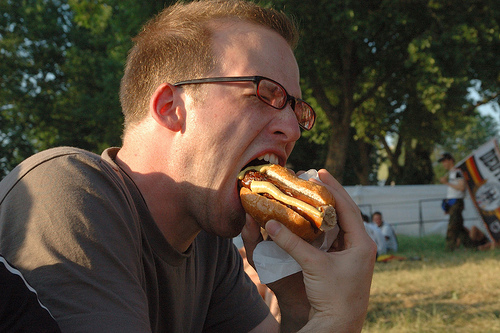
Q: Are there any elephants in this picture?
A: No, there are no elephants.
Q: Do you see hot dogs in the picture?
A: Yes, there is a hot dog.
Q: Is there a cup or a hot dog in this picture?
A: Yes, there is a hot dog.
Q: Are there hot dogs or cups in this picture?
A: Yes, there is a hot dog.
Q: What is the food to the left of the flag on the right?
A: The food is a hot dog.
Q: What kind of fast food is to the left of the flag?
A: The food is a hot dog.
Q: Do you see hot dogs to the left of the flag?
A: Yes, there is a hot dog to the left of the flag.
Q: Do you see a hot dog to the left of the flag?
A: Yes, there is a hot dog to the left of the flag.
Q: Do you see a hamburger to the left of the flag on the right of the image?
A: No, there is a hot dog to the left of the flag.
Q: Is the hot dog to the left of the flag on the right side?
A: Yes, the hot dog is to the left of the flag.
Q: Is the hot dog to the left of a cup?
A: No, the hot dog is to the left of the flag.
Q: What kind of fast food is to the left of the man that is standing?
A: The food is a hot dog.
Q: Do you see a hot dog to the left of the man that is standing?
A: Yes, there is a hot dog to the left of the man.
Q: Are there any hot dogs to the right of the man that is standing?
A: No, the hot dog is to the left of the man.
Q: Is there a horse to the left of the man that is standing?
A: No, there is a hot dog to the left of the man.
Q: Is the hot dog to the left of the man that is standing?
A: Yes, the hot dog is to the left of the man.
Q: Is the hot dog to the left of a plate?
A: No, the hot dog is to the left of the man.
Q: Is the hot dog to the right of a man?
A: No, the hot dog is to the left of a man.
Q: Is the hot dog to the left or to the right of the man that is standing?
A: The hot dog is to the left of the man.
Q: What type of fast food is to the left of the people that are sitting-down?
A: The food is a hot dog.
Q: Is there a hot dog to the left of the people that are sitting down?
A: Yes, there is a hot dog to the left of the people.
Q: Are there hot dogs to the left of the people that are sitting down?
A: Yes, there is a hot dog to the left of the people.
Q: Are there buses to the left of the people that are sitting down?
A: No, there is a hot dog to the left of the people.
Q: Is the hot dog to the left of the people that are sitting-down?
A: Yes, the hot dog is to the left of the people.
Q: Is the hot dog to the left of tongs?
A: No, the hot dog is to the left of the people.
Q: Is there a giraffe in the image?
A: No, there are no giraffes.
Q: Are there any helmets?
A: No, there are no helmets.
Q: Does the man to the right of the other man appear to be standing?
A: Yes, the man is standing.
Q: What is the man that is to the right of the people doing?
A: The man is standing.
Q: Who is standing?
A: The man is standing.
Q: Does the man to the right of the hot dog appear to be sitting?
A: No, the man is standing.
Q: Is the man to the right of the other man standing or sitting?
A: The man is standing.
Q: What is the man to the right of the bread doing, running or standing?
A: The man is standing.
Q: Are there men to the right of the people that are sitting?
A: Yes, there is a man to the right of the people.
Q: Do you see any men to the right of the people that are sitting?
A: Yes, there is a man to the right of the people.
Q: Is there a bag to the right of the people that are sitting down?
A: No, there is a man to the right of the people.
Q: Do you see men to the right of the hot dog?
A: Yes, there is a man to the right of the hot dog.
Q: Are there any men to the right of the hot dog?
A: Yes, there is a man to the right of the hot dog.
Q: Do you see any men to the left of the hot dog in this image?
A: No, the man is to the right of the hot dog.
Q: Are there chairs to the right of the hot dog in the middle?
A: No, there is a man to the right of the hot dog.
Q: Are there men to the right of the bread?
A: Yes, there is a man to the right of the bread.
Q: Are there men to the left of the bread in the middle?
A: No, the man is to the right of the bread.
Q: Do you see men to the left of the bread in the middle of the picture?
A: No, the man is to the right of the bread.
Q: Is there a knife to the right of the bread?
A: No, there is a man to the right of the bread.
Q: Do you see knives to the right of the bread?
A: No, there is a man to the right of the bread.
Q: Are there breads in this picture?
A: Yes, there is a bread.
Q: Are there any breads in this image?
A: Yes, there is a bread.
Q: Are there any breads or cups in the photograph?
A: Yes, there is a bread.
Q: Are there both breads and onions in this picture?
A: No, there is a bread but no onions.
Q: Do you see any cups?
A: No, there are no cups.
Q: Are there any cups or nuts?
A: No, there are no cups or nuts.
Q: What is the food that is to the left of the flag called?
A: The food is a bread.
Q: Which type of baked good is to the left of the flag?
A: The food is a bread.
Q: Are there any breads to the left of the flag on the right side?
A: Yes, there is a bread to the left of the flag.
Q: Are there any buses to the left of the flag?
A: No, there is a bread to the left of the flag.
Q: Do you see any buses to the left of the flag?
A: No, there is a bread to the left of the flag.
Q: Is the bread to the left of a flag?
A: Yes, the bread is to the left of a flag.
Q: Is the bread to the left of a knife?
A: No, the bread is to the left of a flag.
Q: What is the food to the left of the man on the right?
A: The food is a bread.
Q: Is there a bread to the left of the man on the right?
A: Yes, there is a bread to the left of the man.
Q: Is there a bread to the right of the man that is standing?
A: No, the bread is to the left of the man.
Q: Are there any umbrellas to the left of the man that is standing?
A: No, there is a bread to the left of the man.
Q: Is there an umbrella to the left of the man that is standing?
A: No, there is a bread to the left of the man.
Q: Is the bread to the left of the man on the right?
A: Yes, the bread is to the left of the man.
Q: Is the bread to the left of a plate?
A: No, the bread is to the left of the man.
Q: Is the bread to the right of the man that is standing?
A: No, the bread is to the left of the man.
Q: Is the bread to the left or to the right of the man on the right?
A: The bread is to the left of the man.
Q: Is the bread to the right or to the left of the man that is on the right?
A: The bread is to the left of the man.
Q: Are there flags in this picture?
A: Yes, there is a flag.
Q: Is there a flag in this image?
A: Yes, there is a flag.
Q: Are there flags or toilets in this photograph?
A: Yes, there is a flag.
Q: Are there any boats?
A: No, there are no boats.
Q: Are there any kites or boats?
A: No, there are no boats or kites.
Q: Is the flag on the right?
A: Yes, the flag is on the right of the image.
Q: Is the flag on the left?
A: No, the flag is on the right of the image.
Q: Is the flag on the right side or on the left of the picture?
A: The flag is on the right of the image.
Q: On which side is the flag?
A: The flag is on the right of the image.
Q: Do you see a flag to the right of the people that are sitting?
A: Yes, there is a flag to the right of the people.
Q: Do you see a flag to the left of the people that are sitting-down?
A: No, the flag is to the right of the people.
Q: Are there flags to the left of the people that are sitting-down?
A: No, the flag is to the right of the people.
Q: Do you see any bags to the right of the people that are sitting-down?
A: No, there is a flag to the right of the people.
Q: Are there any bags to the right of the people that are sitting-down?
A: No, there is a flag to the right of the people.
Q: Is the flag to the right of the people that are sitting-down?
A: Yes, the flag is to the right of the people.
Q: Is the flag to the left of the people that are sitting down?
A: No, the flag is to the right of the people.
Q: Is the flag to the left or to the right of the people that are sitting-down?
A: The flag is to the right of the people.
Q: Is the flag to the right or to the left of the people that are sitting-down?
A: The flag is to the right of the people.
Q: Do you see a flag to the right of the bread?
A: Yes, there is a flag to the right of the bread.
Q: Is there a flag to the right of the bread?
A: Yes, there is a flag to the right of the bread.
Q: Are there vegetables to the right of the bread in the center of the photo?
A: No, there is a flag to the right of the bread.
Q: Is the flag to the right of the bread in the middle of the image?
A: Yes, the flag is to the right of the bread.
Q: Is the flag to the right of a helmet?
A: No, the flag is to the right of the bread.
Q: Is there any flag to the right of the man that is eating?
A: Yes, there is a flag to the right of the man.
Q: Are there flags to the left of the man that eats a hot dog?
A: No, the flag is to the right of the man.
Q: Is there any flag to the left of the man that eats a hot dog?
A: No, the flag is to the right of the man.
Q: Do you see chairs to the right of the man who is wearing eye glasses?
A: No, there is a flag to the right of the man.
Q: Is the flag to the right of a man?
A: Yes, the flag is to the right of a man.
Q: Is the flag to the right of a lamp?
A: No, the flag is to the right of a man.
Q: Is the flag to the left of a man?
A: No, the flag is to the right of a man.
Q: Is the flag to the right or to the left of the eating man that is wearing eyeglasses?
A: The flag is to the right of the man.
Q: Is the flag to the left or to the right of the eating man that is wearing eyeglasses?
A: The flag is to the right of the man.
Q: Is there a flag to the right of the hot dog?
A: Yes, there is a flag to the right of the hot dog.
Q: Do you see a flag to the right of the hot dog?
A: Yes, there is a flag to the right of the hot dog.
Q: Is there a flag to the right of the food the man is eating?
A: Yes, there is a flag to the right of the hot dog.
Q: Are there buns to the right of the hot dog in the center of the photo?
A: No, there is a flag to the right of the hot dog.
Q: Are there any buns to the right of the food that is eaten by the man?
A: No, there is a flag to the right of the hot dog.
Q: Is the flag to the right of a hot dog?
A: Yes, the flag is to the right of a hot dog.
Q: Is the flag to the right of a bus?
A: No, the flag is to the right of a hot dog.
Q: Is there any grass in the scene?
A: Yes, there is grass.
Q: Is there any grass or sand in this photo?
A: Yes, there is grass.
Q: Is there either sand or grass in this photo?
A: Yes, there is grass.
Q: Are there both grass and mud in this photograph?
A: No, there is grass but no mud.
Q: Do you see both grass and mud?
A: No, there is grass but no mud.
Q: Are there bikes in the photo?
A: No, there are no bikes.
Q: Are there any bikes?
A: No, there are no bikes.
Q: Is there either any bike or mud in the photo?
A: No, there are no bikes or mud.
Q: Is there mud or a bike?
A: No, there are no bikes or mud.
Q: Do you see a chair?
A: No, there are no chairs.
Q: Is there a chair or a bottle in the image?
A: No, there are no chairs or bottles.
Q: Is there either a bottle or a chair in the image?
A: No, there are no chairs or bottles.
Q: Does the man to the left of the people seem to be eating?
A: Yes, the man is eating.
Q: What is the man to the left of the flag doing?
A: The man is eating.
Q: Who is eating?
A: The man is eating.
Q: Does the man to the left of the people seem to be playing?
A: No, the man is eating.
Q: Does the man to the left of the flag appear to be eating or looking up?
A: The man is eating.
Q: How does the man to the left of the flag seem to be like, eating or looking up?
A: The man is eating.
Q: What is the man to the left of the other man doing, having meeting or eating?
A: The man is eating.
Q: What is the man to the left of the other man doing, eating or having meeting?
A: The man is eating.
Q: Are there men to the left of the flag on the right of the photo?
A: Yes, there is a man to the left of the flag.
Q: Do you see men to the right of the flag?
A: No, the man is to the left of the flag.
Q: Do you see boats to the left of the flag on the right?
A: No, there is a man to the left of the flag.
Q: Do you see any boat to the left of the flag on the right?
A: No, there is a man to the left of the flag.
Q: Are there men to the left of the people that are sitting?
A: Yes, there is a man to the left of the people.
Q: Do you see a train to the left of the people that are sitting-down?
A: No, there is a man to the left of the people.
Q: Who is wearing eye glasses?
A: The man is wearing eye glasses.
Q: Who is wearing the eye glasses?
A: The man is wearing eye glasses.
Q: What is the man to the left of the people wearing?
A: The man is wearing eye glasses.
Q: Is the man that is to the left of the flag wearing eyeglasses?
A: Yes, the man is wearing eyeglasses.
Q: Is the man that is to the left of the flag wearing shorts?
A: No, the man is wearing eyeglasses.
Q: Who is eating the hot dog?
A: The man is eating the hot dog.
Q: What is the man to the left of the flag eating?
A: The man is eating a hot dog.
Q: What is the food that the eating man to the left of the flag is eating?
A: The food is a hot dog.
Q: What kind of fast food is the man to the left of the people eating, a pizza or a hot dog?
A: The man is eating a hot dog.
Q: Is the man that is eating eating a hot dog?
A: Yes, the man is eating a hot dog.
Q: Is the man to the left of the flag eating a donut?
A: No, the man is eating a hot dog.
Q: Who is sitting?
A: The people are sitting.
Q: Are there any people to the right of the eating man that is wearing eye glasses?
A: Yes, there are people to the right of the man.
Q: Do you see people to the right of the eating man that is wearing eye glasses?
A: Yes, there are people to the right of the man.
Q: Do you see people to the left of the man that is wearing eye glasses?
A: No, the people are to the right of the man.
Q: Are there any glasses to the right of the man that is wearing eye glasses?
A: No, there are people to the right of the man.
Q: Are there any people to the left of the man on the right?
A: Yes, there are people to the left of the man.